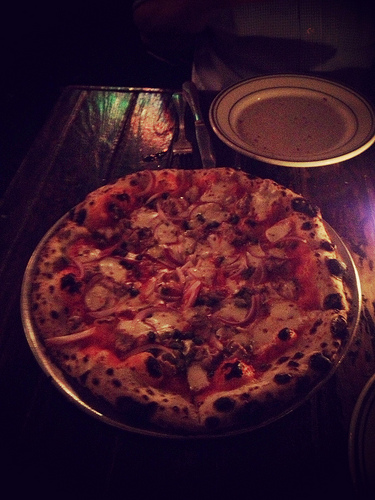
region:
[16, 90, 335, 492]
a cooked pizza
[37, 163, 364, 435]
a cooked pizza on plate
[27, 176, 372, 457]
cooked pizza on a silver platter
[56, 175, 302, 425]
a baked pizza on platter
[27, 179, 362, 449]
a baked pizza on a silver platter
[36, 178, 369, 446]
a pizza sliced into pieces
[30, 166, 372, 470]
a pizza on a table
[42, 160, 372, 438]
a pizza with cheese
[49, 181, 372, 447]
a pizza with tomato sauce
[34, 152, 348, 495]
a plate of pizza on table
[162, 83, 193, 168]
a fork on a table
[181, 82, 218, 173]
a knife on a table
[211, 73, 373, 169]
an empty plate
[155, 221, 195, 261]
melted mozzarella on a pizza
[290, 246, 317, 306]
tomato sauce on a pizza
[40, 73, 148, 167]
a wooden table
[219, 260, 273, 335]
sliced purple onions on a pizza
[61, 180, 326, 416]
a cheese pizza with purple onion slices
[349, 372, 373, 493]
edge of a small white plate with blue lines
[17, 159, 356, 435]
pizza sitting on a pan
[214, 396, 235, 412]
black circle on the crust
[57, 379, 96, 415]
light shining on the edge of the pan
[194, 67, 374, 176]
round white plate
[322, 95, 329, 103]
small crumb on the plate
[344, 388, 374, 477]
edge of a plate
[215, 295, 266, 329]
long topping on the pizza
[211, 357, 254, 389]
bubble on the pizza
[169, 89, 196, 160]
silver fork laying on the table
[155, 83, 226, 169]
knife next to a fork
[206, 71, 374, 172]
a white porcelain plate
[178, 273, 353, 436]
a slice of pizza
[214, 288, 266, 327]
a slice of onion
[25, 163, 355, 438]
a pizza on the platter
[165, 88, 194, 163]
a metal fork on the table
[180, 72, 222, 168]
a metal knife on the table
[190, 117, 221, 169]
the blade of a knife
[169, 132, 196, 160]
the tines of a fork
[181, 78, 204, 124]
the handle of a knife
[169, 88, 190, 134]
the handle of a fork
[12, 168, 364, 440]
THE PIZZA IS ROUND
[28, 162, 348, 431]
THE PIZZA IS SLICED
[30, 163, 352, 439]
THE PIZZA CRUST LOOKS BURNED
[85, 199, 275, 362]
THE PIZZA HAS ONIONS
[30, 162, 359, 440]
THE PIZZA HAS CHEESE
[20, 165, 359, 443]
THE PIZZA HAS RED SAUCE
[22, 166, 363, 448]
THE PIZZA IS ON A PAN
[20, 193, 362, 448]
THE PAN IS SILVER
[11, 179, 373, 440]
THE PAN IS ROUND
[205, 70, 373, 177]
THE PLATE IS EMPTY